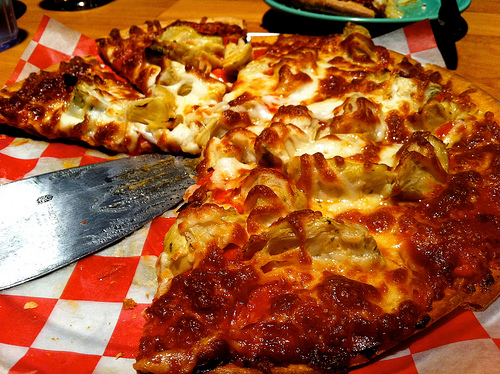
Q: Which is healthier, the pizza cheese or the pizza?
A: The cheese is healthier than the pizza.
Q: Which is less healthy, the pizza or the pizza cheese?
A: The pizza is less healthy than the cheese.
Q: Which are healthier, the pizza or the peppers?
A: The peppers are healthier than the pizza.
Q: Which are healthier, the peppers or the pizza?
A: The peppers are healthier than the pizza.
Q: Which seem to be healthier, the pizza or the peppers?
A: The peppers are healthier than the pizza.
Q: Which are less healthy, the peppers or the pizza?
A: The pizza are less healthy than the peppers.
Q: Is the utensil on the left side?
A: Yes, the utensil is on the left of the image.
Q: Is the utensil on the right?
A: No, the utensil is on the left of the image.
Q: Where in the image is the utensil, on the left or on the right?
A: The utensil is on the left of the image.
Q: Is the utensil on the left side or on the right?
A: The utensil is on the left of the image.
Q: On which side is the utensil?
A: The utensil is on the left of the image.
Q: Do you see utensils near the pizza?
A: Yes, there is a utensil near the pizza.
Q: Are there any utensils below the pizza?
A: Yes, there is a utensil below the pizza.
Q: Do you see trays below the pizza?
A: No, there is a utensil below the pizza.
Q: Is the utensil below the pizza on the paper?
A: Yes, the utensil is below the pizza.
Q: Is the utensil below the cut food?
A: Yes, the utensil is below the pizza.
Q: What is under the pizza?
A: The utensil is under the pizza.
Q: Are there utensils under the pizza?
A: Yes, there is a utensil under the pizza.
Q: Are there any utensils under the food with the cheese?
A: Yes, there is a utensil under the pizza.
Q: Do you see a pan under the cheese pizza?
A: No, there is a utensil under the pizza.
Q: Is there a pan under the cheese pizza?
A: No, there is a utensil under the pizza.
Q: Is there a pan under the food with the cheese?
A: No, there is a utensil under the pizza.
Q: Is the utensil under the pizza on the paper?
A: Yes, the utensil is under the pizza.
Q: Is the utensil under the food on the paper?
A: Yes, the utensil is under the pizza.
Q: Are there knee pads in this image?
A: No, there are no knee pads.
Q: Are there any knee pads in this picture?
A: No, there are no knee pads.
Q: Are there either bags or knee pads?
A: No, there are no knee pads or bags.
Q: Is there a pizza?
A: Yes, there is a pizza.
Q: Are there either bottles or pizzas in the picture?
A: Yes, there is a pizza.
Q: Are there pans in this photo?
A: No, there are no pans.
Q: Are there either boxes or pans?
A: No, there are no pans or boxes.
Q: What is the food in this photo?
A: The food is a pizza.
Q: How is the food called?
A: The food is a pizza.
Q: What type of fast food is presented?
A: The fast food is a pizza.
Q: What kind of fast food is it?
A: The food is a pizza.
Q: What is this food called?
A: This is a pizza.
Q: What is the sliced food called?
A: The food is a pizza.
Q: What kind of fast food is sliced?
A: The fast food is a pizza.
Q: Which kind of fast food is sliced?
A: The fast food is a pizza.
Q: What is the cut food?
A: The food is a pizza.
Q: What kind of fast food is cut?
A: The fast food is a pizza.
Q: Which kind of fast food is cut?
A: The fast food is a pizza.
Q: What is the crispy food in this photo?
A: The food is a pizza.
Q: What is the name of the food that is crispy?
A: The food is a pizza.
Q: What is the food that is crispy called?
A: The food is a pizza.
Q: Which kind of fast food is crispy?
A: The fast food is a pizza.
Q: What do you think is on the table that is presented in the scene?
A: The pizza is on the table.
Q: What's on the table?
A: The pizza is on the table.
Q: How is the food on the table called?
A: The food is a pizza.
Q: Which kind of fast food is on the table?
A: The food is a pizza.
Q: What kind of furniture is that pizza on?
A: The pizza is on the table.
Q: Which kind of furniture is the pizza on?
A: The pizza is on the table.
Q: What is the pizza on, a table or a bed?
A: The pizza is on a table.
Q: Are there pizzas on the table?
A: Yes, there is a pizza on the table.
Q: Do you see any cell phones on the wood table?
A: No, there is a pizza on the table.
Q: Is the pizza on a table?
A: Yes, the pizza is on a table.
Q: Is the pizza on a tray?
A: No, the pizza is on a table.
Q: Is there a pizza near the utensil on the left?
A: Yes, there is a pizza near the utensil.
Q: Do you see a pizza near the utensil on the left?
A: Yes, there is a pizza near the utensil.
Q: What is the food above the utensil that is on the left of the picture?
A: The food is a pizza.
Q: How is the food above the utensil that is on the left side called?
A: The food is a pizza.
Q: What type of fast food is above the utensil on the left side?
A: The food is a pizza.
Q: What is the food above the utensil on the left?
A: The food is a pizza.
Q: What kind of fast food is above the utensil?
A: The food is a pizza.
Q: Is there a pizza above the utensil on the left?
A: Yes, there is a pizza above the utensil.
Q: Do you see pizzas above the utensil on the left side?
A: Yes, there is a pizza above the utensil.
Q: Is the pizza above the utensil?
A: Yes, the pizza is above the utensil.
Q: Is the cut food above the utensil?
A: Yes, the pizza is above the utensil.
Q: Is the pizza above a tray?
A: No, the pizza is above the utensil.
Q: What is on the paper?
A: The pizza is on the paper.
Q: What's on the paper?
A: The pizza is on the paper.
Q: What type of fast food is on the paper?
A: The food is a pizza.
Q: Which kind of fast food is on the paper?
A: The food is a pizza.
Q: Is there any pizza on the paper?
A: Yes, there is a pizza on the paper.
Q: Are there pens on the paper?
A: No, there is a pizza on the paper.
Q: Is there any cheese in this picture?
A: Yes, there is cheese.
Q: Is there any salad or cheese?
A: Yes, there is cheese.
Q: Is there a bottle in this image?
A: No, there are no bottles.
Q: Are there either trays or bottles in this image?
A: No, there are no bottles or trays.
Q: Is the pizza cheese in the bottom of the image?
A: No, the cheese is in the top of the image.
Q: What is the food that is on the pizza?
A: The food is cheese.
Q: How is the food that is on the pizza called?
A: The food is cheese.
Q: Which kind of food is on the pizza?
A: The food is cheese.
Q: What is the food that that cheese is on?
A: The food is a pizza.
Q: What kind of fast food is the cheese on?
A: The cheese is on the pizza.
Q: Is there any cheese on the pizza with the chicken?
A: Yes, there is cheese on the pizza.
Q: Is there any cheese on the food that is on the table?
A: Yes, there is cheese on the pizza.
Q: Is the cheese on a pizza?
A: Yes, the cheese is on a pizza.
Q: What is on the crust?
A: The cheese is on the crust.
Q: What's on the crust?
A: The cheese is on the crust.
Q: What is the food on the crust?
A: The food is cheese.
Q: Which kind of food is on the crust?
A: The food is cheese.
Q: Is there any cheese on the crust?
A: Yes, there is cheese on the crust.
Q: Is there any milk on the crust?
A: No, there is cheese on the crust.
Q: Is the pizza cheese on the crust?
A: Yes, the cheese is on the crust.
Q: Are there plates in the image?
A: Yes, there is a plate.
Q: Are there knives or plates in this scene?
A: Yes, there is a plate.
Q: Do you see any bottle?
A: No, there are no bottles.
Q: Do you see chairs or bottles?
A: No, there are no bottles or chairs.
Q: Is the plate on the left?
A: No, the plate is on the right of the image.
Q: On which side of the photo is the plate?
A: The plate is on the right of the image.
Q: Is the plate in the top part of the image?
A: Yes, the plate is in the top of the image.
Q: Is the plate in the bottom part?
A: No, the plate is in the top of the image.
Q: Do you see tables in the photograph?
A: Yes, there is a table.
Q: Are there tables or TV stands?
A: Yes, there is a table.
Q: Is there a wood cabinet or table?
A: Yes, there is a wood table.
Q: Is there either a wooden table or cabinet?
A: Yes, there is a wood table.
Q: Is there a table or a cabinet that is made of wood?
A: Yes, the table is made of wood.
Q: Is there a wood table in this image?
A: Yes, there is a wood table.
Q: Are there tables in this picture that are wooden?
A: Yes, there is a table that is wooden.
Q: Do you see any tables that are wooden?
A: Yes, there is a table that is wooden.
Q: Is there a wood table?
A: Yes, there is a table that is made of wood.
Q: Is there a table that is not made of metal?
A: Yes, there is a table that is made of wood.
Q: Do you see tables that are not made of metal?
A: Yes, there is a table that is made of wood.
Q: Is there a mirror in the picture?
A: No, there are no mirrors.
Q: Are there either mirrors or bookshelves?
A: No, there are no mirrors or bookshelves.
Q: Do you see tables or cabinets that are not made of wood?
A: No, there is a table but it is made of wood.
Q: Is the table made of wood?
A: Yes, the table is made of wood.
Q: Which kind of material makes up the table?
A: The table is made of wood.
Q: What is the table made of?
A: The table is made of wood.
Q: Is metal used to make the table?
A: No, the table is made of wood.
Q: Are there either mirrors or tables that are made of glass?
A: No, there is a table but it is made of wood.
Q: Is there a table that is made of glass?
A: No, there is a table but it is made of wood.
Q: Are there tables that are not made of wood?
A: No, there is a table but it is made of wood.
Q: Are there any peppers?
A: Yes, there are peppers.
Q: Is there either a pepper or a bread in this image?
A: Yes, there are peppers.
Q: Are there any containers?
A: No, there are no containers.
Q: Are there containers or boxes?
A: No, there are no containers or boxes.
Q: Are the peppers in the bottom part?
A: Yes, the peppers are in the bottom of the image.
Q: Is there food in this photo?
A: Yes, there is food.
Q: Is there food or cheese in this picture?
A: Yes, there is food.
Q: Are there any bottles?
A: No, there are no bottles.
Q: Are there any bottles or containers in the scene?
A: No, there are no bottles or containers.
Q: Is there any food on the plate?
A: Yes, there is food on the plate.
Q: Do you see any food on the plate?
A: Yes, there is food on the plate.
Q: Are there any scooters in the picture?
A: No, there are no scooters.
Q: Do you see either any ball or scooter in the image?
A: No, there are no scooters or balls.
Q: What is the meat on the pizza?
A: The meat is chicken.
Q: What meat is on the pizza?
A: The meat is chicken.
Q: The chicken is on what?
A: The chicken is on the pizza.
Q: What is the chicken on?
A: The chicken is on the pizza.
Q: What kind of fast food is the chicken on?
A: The chicken is on the pizza.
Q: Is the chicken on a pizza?
A: Yes, the chicken is on a pizza.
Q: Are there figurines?
A: No, there are no figurines.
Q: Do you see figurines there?
A: No, there are no figurines.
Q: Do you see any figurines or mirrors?
A: No, there are no figurines or mirrors.